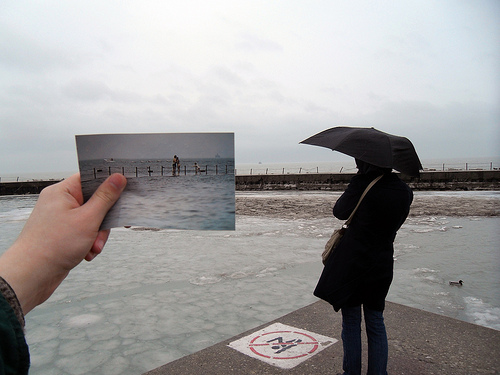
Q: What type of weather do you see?
A: It is cloudy.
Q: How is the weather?
A: It is cloudy.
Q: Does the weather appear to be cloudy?
A: Yes, it is cloudy.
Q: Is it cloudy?
A: Yes, it is cloudy.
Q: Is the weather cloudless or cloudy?
A: It is cloudy.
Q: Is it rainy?
A: No, it is cloudy.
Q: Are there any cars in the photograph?
A: No, there are no cars.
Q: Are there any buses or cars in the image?
A: No, there are no cars or buses.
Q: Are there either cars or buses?
A: No, there are no cars or buses.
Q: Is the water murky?
A: Yes, the water is murky.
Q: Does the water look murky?
A: Yes, the water is murky.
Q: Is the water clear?
A: No, the water is murky.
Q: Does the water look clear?
A: No, the water is murky.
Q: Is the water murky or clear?
A: The water is murky.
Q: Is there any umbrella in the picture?
A: Yes, there is an umbrella.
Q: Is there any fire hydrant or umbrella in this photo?
A: Yes, there is an umbrella.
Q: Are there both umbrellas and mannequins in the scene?
A: No, there is an umbrella but no mannequins.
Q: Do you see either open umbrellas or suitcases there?
A: Yes, there is an open umbrella.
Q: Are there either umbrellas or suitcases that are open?
A: Yes, the umbrella is open.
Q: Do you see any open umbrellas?
A: Yes, there is an open umbrella.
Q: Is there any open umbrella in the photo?
A: Yes, there is an open umbrella.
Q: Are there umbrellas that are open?
A: Yes, there is an umbrella that is open.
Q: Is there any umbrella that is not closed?
A: Yes, there is a open umbrella.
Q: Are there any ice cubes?
A: No, there are no ice cubes.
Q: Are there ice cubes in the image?
A: No, there are no ice cubes.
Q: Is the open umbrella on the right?
A: Yes, the umbrella is on the right of the image.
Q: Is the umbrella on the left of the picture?
A: No, the umbrella is on the right of the image.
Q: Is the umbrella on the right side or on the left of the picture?
A: The umbrella is on the right of the image.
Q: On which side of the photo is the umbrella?
A: The umbrella is on the right of the image.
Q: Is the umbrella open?
A: Yes, the umbrella is open.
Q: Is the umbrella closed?
A: No, the umbrella is open.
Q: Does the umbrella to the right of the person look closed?
A: No, the umbrella is open.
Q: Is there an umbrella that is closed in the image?
A: No, there is an umbrella but it is open.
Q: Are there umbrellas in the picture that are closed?
A: No, there is an umbrella but it is open.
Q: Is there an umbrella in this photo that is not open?
A: No, there is an umbrella but it is open.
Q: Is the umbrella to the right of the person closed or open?
A: The umbrella is open.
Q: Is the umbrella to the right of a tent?
A: No, the umbrella is to the right of a person.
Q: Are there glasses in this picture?
A: No, there are no glasses.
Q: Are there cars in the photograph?
A: No, there are no cars.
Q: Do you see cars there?
A: No, there are no cars.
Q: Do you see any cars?
A: No, there are no cars.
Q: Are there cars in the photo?
A: No, there are no cars.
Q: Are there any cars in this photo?
A: No, there are no cars.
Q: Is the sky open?
A: Yes, the sky is open.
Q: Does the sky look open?
A: Yes, the sky is open.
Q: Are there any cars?
A: No, there are no cars.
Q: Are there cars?
A: No, there are no cars.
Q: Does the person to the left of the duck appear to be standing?
A: Yes, the person is standing.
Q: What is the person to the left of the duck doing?
A: The person is standing.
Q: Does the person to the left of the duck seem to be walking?
A: No, the person is standing.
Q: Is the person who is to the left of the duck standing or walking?
A: The person is standing.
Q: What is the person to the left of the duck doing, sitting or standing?
A: The person is standing.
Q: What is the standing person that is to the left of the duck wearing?
A: The person is wearing jeans.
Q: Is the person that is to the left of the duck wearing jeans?
A: Yes, the person is wearing jeans.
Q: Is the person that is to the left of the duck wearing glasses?
A: No, the person is wearing jeans.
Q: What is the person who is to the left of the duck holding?
A: The person is holding the umbrella.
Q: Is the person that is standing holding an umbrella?
A: Yes, the person is holding an umbrella.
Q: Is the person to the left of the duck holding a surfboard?
A: No, the person is holding an umbrella.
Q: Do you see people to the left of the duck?
A: Yes, there is a person to the left of the duck.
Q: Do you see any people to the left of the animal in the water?
A: Yes, there is a person to the left of the duck.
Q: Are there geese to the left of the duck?
A: No, there is a person to the left of the duck.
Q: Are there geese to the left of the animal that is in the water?
A: No, there is a person to the left of the duck.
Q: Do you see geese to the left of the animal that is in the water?
A: No, there is a person to the left of the duck.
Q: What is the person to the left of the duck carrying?
A: The person is carrying an umbrella.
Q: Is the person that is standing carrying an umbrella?
A: Yes, the person is carrying an umbrella.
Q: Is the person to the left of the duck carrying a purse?
A: No, the person is carrying an umbrella.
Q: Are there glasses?
A: No, there are no glasses.